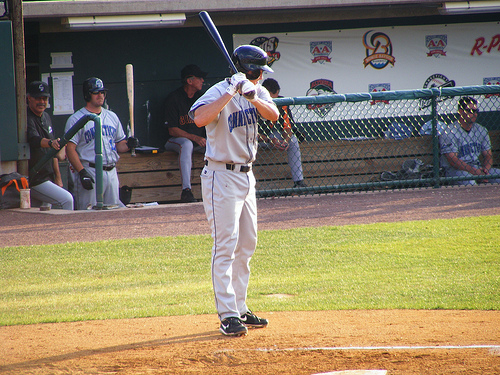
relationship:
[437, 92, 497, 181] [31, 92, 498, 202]
baseball player seated in dugout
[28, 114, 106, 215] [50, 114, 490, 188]
green rail along dugout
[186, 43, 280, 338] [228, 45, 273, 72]
baseball player wearing helmet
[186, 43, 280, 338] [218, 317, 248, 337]
baseball player wearing shoe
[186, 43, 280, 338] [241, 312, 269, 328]
baseball player wearing shoe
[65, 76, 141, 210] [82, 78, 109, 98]
baseball player wearing helmet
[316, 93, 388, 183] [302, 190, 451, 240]
fence surrounds field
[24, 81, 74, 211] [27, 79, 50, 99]
man wearing cap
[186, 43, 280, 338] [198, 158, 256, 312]
baseball player wearing gray pants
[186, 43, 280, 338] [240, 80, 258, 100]
baseball player wearing glove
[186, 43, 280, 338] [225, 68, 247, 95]
baseball player wearing glove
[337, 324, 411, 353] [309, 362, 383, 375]
dirt near home plate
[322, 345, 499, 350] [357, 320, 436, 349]
line drawn in dirt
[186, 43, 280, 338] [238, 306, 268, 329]
baseball player wearing shoe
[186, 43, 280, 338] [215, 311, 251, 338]
baseball player wearing shoe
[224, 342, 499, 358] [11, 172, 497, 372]
line on field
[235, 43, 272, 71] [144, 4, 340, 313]
helmet on batter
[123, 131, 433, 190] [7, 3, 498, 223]
bench in dugout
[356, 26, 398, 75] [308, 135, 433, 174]
logo above bench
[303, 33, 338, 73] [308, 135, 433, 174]
logo above bench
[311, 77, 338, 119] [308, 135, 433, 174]
logo above bench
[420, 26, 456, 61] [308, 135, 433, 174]
logo above bench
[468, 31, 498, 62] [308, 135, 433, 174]
logo above bench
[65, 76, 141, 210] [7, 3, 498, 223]
baseball player by dugout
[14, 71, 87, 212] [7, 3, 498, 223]
coach by dugout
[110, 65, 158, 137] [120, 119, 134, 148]
bat in hand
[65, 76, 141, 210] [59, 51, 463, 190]
baseball player in dugout